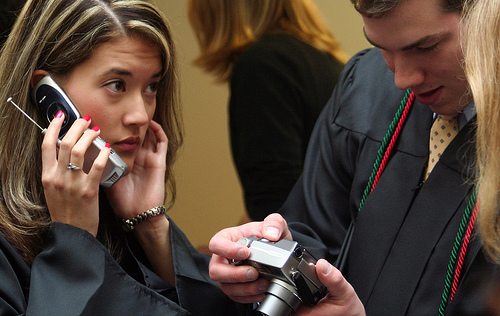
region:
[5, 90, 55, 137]
grey antenna on cell phone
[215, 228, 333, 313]
silver handheld camera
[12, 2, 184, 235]
woman with blond and brown hair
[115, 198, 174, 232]
small metal bracelet on wrist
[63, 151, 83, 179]
small metal ring on finger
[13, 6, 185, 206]
woman on the phone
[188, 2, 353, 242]
woman wearing black jacket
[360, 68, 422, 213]
green and red cord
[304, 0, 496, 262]
man wearing black jacket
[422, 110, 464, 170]
gold tie with blue spots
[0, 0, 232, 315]
The young lady with a cell phone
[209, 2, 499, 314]
The man holding a camera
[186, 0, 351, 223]
The woman with blonde hair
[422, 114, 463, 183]
A yellow and black spotted tie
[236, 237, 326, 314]
A gray automatic camera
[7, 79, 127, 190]
A flip phone with an antenna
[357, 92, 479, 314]
Green and red straps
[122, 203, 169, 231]
A twisted arm band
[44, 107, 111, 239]
The hand with red manicure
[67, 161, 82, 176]
The hand with a ring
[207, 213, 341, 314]
silver metal camera being held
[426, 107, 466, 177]
grey and orange neck tie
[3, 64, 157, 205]
grey cellphone in hand of woman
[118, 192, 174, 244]
gold wristwatch on woman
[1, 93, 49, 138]
antenna on cellphone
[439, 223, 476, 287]
red and green rope around neck of man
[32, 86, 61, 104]
company logo on front of cellphone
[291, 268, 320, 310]
black carry strap on side of camera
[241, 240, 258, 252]
red power light on top of camera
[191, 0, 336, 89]
woman with brown hair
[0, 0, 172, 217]
a girl is on a flip phone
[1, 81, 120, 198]
an antenna is up on the cellphone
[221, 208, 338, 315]
a boy has a camera in his hands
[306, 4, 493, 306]
the boy is wearing honor cords on his gown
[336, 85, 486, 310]
the cords are green and red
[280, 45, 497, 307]
the graduation gown is black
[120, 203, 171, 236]
the girl is wearing a watch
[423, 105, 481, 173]
the graduate is wearing a shirt and tie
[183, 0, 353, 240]
a girl is in the background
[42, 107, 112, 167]
the graduate is wearing red nail polish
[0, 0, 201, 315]
lady with blonde highlights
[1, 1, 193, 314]
lady on the cellphone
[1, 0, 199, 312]
lady wearing a bracelet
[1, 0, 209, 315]
lady wearing a ring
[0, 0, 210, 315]
lady with painted red nails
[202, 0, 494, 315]
guy holding a camera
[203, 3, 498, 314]
guy looking at the camera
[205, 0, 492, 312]
guy wearing a yellow tie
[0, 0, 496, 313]
Two graduating students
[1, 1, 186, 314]
girl looking away